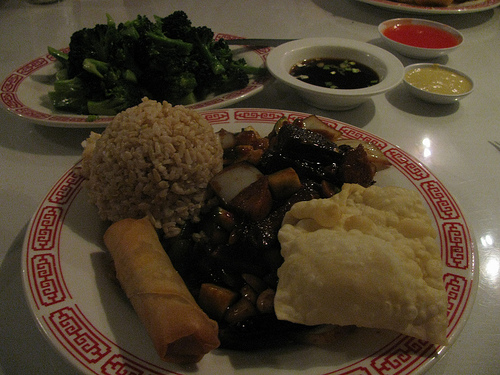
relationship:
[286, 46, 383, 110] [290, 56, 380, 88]
bowl of sauce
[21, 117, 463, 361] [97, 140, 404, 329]
plate of food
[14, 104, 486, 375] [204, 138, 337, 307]
plate of meat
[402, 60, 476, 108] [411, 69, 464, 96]
bowl of mustard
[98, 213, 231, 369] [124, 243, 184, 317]
roll of egg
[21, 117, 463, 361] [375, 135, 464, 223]
plate with pattern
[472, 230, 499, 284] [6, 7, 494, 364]
light on table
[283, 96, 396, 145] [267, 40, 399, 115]
shadow of bowl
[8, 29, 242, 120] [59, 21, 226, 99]
plate of broccoli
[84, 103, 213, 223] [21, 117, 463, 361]
rice on plate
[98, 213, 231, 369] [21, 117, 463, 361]
roll on plate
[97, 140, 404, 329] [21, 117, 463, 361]
dinner on plate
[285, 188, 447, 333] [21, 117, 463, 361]
chip on plate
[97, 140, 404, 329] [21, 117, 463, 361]
food on plate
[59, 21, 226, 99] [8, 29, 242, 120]
broccoli on plate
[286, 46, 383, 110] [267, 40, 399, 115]
soup in bowl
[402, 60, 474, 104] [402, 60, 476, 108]
sauce in bowl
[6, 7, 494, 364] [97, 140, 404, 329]
table with food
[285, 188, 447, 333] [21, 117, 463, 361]
dumpling on plate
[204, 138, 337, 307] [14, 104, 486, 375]
meat on plate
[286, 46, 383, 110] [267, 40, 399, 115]
sauce in dish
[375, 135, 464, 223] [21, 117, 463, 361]
design on plate